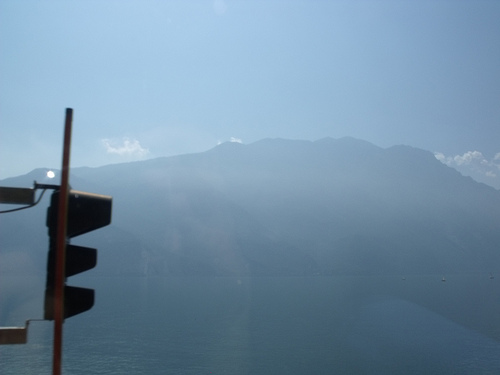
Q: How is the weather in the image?
A: It is clear.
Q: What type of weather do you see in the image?
A: It is clear.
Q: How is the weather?
A: It is clear.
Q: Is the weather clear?
A: Yes, it is clear.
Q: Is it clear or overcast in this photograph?
A: It is clear.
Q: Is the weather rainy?
A: No, it is clear.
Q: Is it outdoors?
A: Yes, it is outdoors.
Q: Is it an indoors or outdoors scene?
A: It is outdoors.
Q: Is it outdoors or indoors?
A: It is outdoors.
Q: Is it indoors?
A: No, it is outdoors.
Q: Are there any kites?
A: No, there are no kites.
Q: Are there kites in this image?
A: No, there are no kites.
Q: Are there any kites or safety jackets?
A: No, there are no kites or safety jackets.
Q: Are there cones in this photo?
A: No, there are no cones.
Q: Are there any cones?
A: No, there are no cones.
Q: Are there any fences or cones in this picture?
A: No, there are no cones or fences.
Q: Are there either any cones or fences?
A: No, there are no cones or fences.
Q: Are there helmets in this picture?
A: No, there are no helmets.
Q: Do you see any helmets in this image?
A: No, there are no helmets.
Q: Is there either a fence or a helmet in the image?
A: No, there are no helmets or fences.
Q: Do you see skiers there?
A: No, there are no skiers.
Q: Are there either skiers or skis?
A: No, there are no skiers or skis.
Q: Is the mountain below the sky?
A: Yes, the mountain is below the sky.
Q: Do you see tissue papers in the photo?
A: No, there are no tissue papers.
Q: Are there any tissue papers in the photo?
A: No, there are no tissue papers.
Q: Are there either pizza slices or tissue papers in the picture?
A: No, there are no tissue papers or pizza slices.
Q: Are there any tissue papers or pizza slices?
A: No, there are no tissue papers or pizza slices.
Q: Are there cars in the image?
A: No, there are no cars.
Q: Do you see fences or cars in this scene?
A: No, there are no cars or fences.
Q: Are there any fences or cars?
A: No, there are no cars or fences.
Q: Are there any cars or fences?
A: No, there are no cars or fences.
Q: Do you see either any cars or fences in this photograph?
A: No, there are no cars or fences.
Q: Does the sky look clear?
A: Yes, the sky is clear.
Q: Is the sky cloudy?
A: No, the sky is clear.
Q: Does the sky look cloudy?
A: No, the sky is clear.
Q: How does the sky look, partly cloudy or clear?
A: The sky is clear.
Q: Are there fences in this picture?
A: No, there are no fences.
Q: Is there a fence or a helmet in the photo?
A: No, there are no fences or helmets.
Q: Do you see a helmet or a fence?
A: No, there are no fences or helmets.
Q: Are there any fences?
A: No, there are no fences.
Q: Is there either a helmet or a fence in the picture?
A: No, there are no fences or helmets.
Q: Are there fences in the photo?
A: No, there are no fences.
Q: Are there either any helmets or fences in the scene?
A: No, there are no fences or helmets.